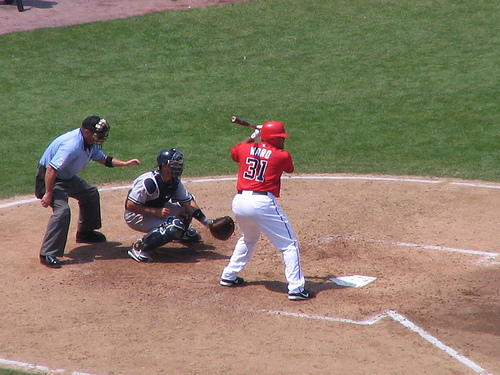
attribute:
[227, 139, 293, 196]
shirt — red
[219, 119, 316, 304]
batter — getting ready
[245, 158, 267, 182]
number — black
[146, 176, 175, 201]
pads — black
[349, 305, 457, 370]
lines — white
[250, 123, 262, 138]
glove — white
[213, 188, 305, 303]
uniform — white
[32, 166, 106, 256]
pants — grey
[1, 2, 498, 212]
grass — green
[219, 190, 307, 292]
pants — white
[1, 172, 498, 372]
dirt — brown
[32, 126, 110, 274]
suit — blue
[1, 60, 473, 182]
grass — fresh-cut, green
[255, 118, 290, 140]
helmet — red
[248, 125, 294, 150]
helmet — red